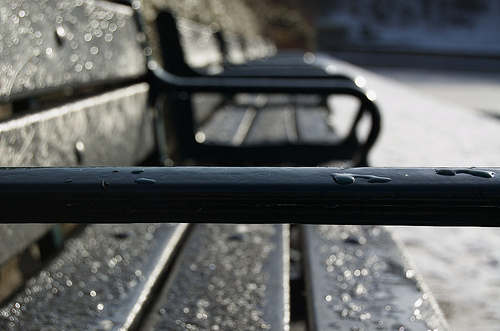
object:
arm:
[303, 78, 358, 94]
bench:
[144, 7, 380, 167]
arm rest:
[151, 65, 366, 99]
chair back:
[0, 0, 167, 294]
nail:
[70, 52, 95, 72]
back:
[165, 91, 202, 157]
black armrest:
[146, 57, 366, 93]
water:
[66, 11, 109, 76]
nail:
[341, 233, 366, 245]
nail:
[228, 227, 248, 242]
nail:
[110, 227, 130, 240]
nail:
[53, 27, 66, 44]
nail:
[76, 139, 85, 156]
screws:
[56, 22, 69, 46]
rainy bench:
[0, 0, 496, 329]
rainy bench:
[147, 7, 373, 159]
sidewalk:
[378, 50, 495, 327]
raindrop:
[356, 175, 392, 182]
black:
[329, 168, 497, 213]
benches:
[0, 0, 449, 330]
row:
[0, 80, 160, 270]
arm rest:
[0, 165, 500, 226]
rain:
[435, 167, 494, 180]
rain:
[337, 248, 400, 308]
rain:
[339, 273, 366, 318]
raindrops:
[208, 270, 256, 325]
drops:
[331, 171, 354, 185]